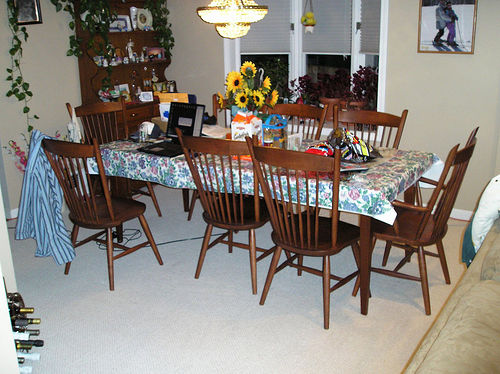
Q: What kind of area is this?
A: Diningroom.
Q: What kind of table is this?
A: Dining room.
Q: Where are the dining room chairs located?
A: Table.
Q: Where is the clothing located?
A: Chair.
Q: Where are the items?
A: Table.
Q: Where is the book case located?
A: Dining room.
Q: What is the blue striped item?
A: Shirt.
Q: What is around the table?
A: Chairs.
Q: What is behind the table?
A: A window.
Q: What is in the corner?
A: A china hutch.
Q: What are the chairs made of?
A: Wood.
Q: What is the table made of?
A: Wood.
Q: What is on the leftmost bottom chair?
A: A shirt.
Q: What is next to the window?
A: A picture.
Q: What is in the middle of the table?
A: Flowers.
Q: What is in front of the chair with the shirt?
A: A laptop.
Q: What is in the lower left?
A: Wine bottles.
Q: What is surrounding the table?
A: Chairs.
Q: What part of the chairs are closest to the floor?
A: The legs.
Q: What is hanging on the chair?
A: A shirt.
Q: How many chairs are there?
A: 8.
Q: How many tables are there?
A: 1.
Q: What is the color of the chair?
A: Brown.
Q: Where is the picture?
A: In the wall.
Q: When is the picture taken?
A: Nighttime.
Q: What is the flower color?
A: Yellow.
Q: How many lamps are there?
A: One.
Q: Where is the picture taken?
A: In the dining room.